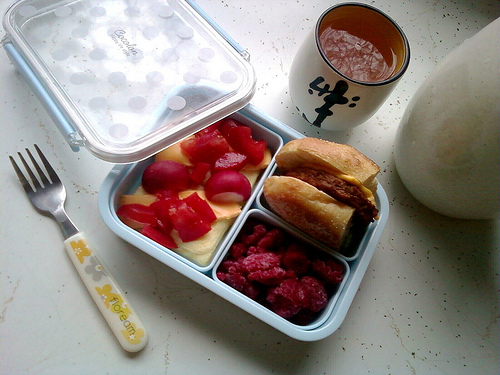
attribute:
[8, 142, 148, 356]
fork — little, plastic, silver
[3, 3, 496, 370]
table — white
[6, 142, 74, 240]
fork prongs — silver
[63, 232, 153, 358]
handle — gray, yellow, white, plastic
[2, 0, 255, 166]
top — white, plastic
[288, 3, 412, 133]
cup — white, black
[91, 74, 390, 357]
dish — blue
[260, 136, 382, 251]
sandwich — cut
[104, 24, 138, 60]
letters — black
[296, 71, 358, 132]
image — black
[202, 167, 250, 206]
radish — cut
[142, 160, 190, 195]
radish — cut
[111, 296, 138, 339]
letters — black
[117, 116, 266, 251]
peppers — cut, red